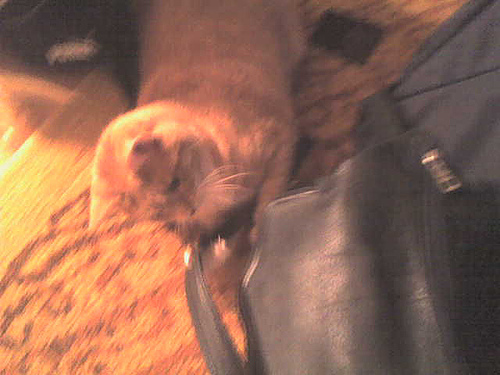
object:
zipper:
[420, 147, 462, 194]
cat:
[87, 0, 308, 234]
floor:
[0, 353, 51, 375]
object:
[307, 7, 385, 65]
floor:
[0, 208, 44, 287]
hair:
[193, 108, 233, 167]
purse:
[184, 129, 477, 375]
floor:
[0, 66, 38, 121]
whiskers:
[196, 164, 253, 210]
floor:
[134, 323, 180, 373]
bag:
[183, 127, 473, 374]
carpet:
[3, 129, 251, 370]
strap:
[182, 237, 246, 375]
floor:
[90, 255, 182, 288]